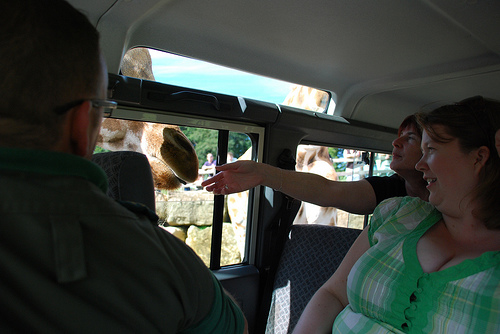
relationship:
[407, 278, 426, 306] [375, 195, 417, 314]
buttons are on a shirt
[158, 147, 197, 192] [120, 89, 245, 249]
mouth in window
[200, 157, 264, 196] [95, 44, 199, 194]
hand near a giraffe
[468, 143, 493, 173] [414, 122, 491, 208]
ear on face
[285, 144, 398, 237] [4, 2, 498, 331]
window in car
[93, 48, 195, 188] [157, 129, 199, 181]
giraffe has nose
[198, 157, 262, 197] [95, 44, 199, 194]
hand near giraffe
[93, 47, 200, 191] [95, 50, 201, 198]
giraffe has head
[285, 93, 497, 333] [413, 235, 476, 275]
woman has cleavage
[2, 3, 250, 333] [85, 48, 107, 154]
man has face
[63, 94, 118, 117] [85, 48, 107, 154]
glasses on face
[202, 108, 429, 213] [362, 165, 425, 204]
person wearing tee shirt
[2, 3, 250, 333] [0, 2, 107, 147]
man has hair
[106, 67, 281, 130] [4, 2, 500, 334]
handle in car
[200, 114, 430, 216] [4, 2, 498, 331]
woman sitting in car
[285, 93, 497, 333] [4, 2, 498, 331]
woman sitting in car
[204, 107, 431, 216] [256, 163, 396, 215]
woman has arm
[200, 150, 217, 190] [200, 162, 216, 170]
person wearing shirt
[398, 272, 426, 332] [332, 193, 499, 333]
buttons on front of shirt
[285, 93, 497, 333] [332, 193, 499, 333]
woman wearing shirt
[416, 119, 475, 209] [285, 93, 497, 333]
face of a woman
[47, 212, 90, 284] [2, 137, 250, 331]
loop on shirt